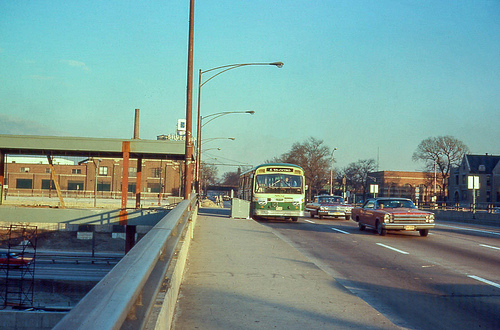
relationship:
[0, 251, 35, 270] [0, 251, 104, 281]
car on road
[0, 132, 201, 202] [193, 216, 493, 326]
building across road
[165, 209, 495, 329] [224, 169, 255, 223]
street at bus stop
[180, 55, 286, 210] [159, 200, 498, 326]
street lights are hanging over street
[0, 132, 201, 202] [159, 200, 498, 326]
building are on side of street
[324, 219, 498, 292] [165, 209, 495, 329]
lines are painted on street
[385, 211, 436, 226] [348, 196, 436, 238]
bumper on car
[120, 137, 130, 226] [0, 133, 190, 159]
beam holding up roof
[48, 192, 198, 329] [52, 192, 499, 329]
railing on side of bridge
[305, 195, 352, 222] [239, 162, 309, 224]
car beside bus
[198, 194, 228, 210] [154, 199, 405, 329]
construction area on sidewalk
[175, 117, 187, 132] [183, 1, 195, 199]
sign behind pole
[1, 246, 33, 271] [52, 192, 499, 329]
car driving under bridge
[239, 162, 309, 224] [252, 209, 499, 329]
bus driving on street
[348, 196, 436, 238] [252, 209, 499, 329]
car driving on street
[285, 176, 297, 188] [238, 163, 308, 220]
driver in bus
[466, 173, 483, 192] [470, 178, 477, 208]
sign on pole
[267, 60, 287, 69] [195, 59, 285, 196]
street lights on lamp post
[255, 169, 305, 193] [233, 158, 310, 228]
windshield on bus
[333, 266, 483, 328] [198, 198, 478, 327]
shadow on road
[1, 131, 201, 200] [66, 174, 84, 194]
building has window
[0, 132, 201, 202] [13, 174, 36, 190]
building has glass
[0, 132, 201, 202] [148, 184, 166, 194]
building has window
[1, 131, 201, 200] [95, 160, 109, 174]
building has window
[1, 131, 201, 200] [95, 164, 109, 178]
building has window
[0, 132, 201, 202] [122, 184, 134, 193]
building has window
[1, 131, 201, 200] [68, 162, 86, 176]
building has window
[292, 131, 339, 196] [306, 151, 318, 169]
tree has leaves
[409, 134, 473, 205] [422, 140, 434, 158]
tree has leaves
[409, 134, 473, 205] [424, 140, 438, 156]
tree has leaves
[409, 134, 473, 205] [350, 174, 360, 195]
tree has leaves